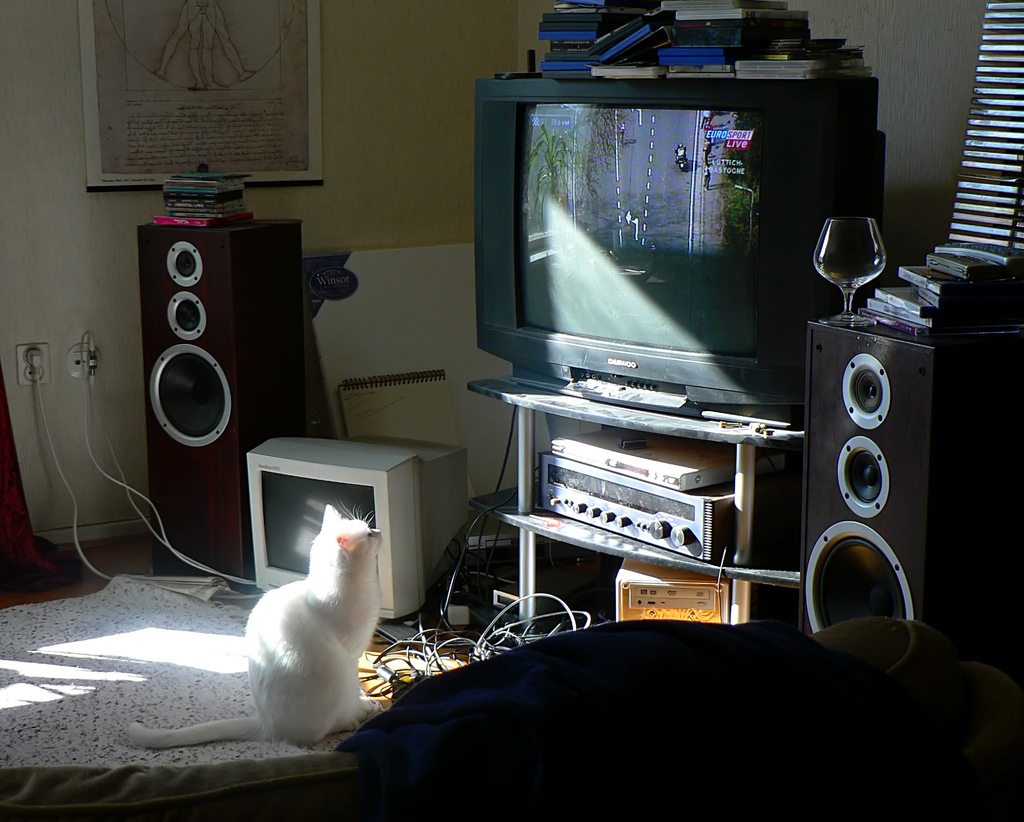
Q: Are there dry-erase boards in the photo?
A: No, there are no dry-erase boards.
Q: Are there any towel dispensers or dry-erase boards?
A: No, there are no dry-erase boards or towel dispensers.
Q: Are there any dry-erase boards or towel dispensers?
A: No, there are no dry-erase boards or towel dispensers.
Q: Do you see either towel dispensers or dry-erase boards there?
A: No, there are no dry-erase boards or towel dispensers.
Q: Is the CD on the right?
A: Yes, the CD is on the right of the image.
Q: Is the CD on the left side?
A: No, the CD is on the right of the image.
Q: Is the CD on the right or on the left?
A: The CD is on the right of the image.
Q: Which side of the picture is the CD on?
A: The CD is on the right of the image.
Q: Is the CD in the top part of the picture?
A: Yes, the CD is in the top of the image.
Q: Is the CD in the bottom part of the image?
A: No, the CD is in the top of the image.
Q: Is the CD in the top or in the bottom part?
A: The CD is in the top of the image.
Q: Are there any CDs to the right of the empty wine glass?
A: Yes, there is a CD to the right of the wine glass.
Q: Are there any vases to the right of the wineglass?
A: No, there is a CD to the right of the wineglass.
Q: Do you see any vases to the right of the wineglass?
A: No, there is a CD to the right of the wineglass.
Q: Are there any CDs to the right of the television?
A: Yes, there is a CD to the right of the television.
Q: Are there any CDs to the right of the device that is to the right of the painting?
A: Yes, there is a CD to the right of the television.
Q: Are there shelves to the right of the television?
A: No, there is a CD to the right of the television.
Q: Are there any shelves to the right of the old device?
A: No, there is a CD to the right of the television.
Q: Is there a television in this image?
A: Yes, there is a television.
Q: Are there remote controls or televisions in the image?
A: Yes, there is a television.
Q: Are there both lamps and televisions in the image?
A: No, there is a television but no lamps.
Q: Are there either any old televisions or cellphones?
A: Yes, there is an old television.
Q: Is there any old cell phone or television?
A: Yes, there is an old television.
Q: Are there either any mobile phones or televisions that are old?
A: Yes, the television is old.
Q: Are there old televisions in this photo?
A: Yes, there is an old television.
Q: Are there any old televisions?
A: Yes, there is an old television.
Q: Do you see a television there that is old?
A: Yes, there is a television that is old.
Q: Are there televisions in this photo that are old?
A: Yes, there is a television that is old.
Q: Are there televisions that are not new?
A: Yes, there is a old television.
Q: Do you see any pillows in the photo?
A: No, there are no pillows.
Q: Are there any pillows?
A: No, there are no pillows.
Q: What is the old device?
A: The device is a television.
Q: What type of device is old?
A: The device is a television.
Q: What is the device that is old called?
A: The device is a television.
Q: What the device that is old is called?
A: The device is a television.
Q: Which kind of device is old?
A: The device is a television.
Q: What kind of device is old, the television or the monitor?
A: The television is old.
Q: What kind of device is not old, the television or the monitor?
A: The monitor is not old.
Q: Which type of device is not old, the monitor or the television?
A: The monitor is not old.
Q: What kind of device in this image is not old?
A: The device is a monitor.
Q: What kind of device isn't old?
A: The device is a monitor.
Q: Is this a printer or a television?
A: This is a television.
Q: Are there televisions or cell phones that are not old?
A: No, there is a television but it is old.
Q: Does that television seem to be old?
A: Yes, the television is old.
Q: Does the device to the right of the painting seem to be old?
A: Yes, the television is old.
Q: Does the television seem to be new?
A: No, the television is old.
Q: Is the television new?
A: No, the television is old.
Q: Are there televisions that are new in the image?
A: No, there is a television but it is old.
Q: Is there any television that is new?
A: No, there is a television but it is old.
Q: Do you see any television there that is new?
A: No, there is a television but it is old.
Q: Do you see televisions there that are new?
A: No, there is a television but it is old.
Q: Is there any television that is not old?
A: No, there is a television but it is old.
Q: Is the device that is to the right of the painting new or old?
A: The TV is old.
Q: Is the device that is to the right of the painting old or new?
A: The TV is old.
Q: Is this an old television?
A: Yes, this is an old television.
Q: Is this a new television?
A: No, this is an old television.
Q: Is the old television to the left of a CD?
A: Yes, the television is to the left of a CD.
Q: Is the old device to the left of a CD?
A: Yes, the television is to the left of a CD.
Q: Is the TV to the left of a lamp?
A: No, the TV is to the left of a CD.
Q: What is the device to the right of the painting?
A: The device is a television.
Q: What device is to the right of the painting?
A: The device is a television.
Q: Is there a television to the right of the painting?
A: Yes, there is a television to the right of the painting.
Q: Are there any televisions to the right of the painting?
A: Yes, there is a television to the right of the painting.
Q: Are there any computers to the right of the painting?
A: No, there is a television to the right of the painting.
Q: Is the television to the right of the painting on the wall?
A: Yes, the television is to the right of the painting.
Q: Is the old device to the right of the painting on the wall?
A: Yes, the television is to the right of the painting.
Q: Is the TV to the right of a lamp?
A: No, the TV is to the right of the painting.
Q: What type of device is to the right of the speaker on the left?
A: The device is a television.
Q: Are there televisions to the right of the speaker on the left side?
A: Yes, there is a television to the right of the speaker.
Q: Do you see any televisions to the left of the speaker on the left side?
A: No, the television is to the right of the speaker.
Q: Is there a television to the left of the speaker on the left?
A: No, the television is to the right of the speaker.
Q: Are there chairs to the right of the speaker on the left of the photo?
A: No, there is a television to the right of the speaker.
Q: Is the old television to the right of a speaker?
A: Yes, the television is to the right of a speaker.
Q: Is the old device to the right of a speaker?
A: Yes, the television is to the right of a speaker.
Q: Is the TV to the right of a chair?
A: No, the TV is to the right of a speaker.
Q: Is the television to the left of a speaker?
A: No, the television is to the right of a speaker.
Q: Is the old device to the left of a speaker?
A: No, the television is to the right of a speaker.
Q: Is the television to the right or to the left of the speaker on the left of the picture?
A: The television is to the right of the speaker.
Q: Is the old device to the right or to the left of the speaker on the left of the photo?
A: The television is to the right of the speaker.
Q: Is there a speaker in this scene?
A: Yes, there is a speaker.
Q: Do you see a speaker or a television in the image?
A: Yes, there is a speaker.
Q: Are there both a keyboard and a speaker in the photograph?
A: No, there is a speaker but no keyboards.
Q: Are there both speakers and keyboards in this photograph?
A: No, there is a speaker but no keyboards.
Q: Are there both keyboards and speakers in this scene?
A: No, there is a speaker but no keyboards.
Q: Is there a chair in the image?
A: No, there are no chairs.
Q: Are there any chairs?
A: No, there are no chairs.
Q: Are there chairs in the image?
A: No, there are no chairs.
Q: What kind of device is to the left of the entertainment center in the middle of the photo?
A: The device is a speaker.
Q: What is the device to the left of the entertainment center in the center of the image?
A: The device is a speaker.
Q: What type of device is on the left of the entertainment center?
A: The device is a speaker.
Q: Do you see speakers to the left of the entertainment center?
A: Yes, there is a speaker to the left of the entertainment center.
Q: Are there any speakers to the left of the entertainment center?
A: Yes, there is a speaker to the left of the entertainment center.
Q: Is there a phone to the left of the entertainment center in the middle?
A: No, there is a speaker to the left of the entertainment center.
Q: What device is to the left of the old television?
A: The device is a speaker.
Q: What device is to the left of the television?
A: The device is a speaker.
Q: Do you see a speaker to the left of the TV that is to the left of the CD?
A: Yes, there is a speaker to the left of the TV.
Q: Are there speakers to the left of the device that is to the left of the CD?
A: Yes, there is a speaker to the left of the TV.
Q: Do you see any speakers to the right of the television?
A: No, the speaker is to the left of the television.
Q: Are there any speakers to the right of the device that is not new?
A: No, the speaker is to the left of the television.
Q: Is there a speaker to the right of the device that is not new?
A: No, the speaker is to the left of the television.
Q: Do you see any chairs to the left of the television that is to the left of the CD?
A: No, there is a speaker to the left of the television.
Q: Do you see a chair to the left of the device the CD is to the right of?
A: No, there is a speaker to the left of the television.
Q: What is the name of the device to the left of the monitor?
A: The device is a speaker.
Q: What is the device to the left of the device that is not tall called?
A: The device is a speaker.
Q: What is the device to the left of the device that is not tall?
A: The device is a speaker.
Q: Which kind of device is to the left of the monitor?
A: The device is a speaker.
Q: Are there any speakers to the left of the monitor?
A: Yes, there is a speaker to the left of the monitor.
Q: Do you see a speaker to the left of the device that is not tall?
A: Yes, there is a speaker to the left of the monitor.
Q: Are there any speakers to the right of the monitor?
A: No, the speaker is to the left of the monitor.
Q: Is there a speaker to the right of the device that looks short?
A: No, the speaker is to the left of the monitor.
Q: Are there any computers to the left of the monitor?
A: No, there is a speaker to the left of the monitor.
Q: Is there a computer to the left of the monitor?
A: No, there is a speaker to the left of the monitor.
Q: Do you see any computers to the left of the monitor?
A: No, there is a speaker to the left of the monitor.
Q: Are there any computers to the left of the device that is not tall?
A: No, there is a speaker to the left of the monitor.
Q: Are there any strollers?
A: No, there are no strollers.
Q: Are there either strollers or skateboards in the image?
A: No, there are no strollers or skateboards.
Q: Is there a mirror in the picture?
A: No, there are no mirrors.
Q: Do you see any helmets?
A: No, there are no helmets.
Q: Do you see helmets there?
A: No, there are no helmets.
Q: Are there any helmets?
A: No, there are no helmets.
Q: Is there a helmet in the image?
A: No, there are no helmets.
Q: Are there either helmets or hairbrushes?
A: No, there are no helmets or hairbrushes.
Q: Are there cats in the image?
A: Yes, there is a cat.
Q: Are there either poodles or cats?
A: Yes, there is a cat.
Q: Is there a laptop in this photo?
A: No, there are no laptops.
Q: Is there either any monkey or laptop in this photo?
A: No, there are no laptops or monkeys.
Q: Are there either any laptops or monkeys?
A: No, there are no laptops or monkeys.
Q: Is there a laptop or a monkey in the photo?
A: No, there are no laptops or monkeys.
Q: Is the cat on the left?
A: Yes, the cat is on the left of the image.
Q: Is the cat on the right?
A: No, the cat is on the left of the image.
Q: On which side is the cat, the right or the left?
A: The cat is on the left of the image.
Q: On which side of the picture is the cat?
A: The cat is on the left of the image.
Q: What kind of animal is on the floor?
A: The animal is a cat.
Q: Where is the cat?
A: The cat is on the floor.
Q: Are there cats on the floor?
A: Yes, there is a cat on the floor.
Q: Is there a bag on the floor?
A: No, there is a cat on the floor.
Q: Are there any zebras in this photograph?
A: No, there are no zebras.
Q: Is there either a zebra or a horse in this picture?
A: No, there are no zebras or horses.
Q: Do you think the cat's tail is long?
A: Yes, the tail is long.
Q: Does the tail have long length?
A: Yes, the tail is long.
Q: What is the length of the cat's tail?
A: The tail is long.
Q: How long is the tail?
A: The tail is long.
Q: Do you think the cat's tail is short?
A: No, the tail is long.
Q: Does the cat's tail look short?
A: No, the tail is long.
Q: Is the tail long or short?
A: The tail is long.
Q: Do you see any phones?
A: No, there are no phones.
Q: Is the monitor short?
A: Yes, the monitor is short.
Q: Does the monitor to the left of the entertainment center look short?
A: Yes, the monitor is short.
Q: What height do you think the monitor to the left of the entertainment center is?
A: The monitor is short.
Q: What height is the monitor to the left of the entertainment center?
A: The monitor is short.